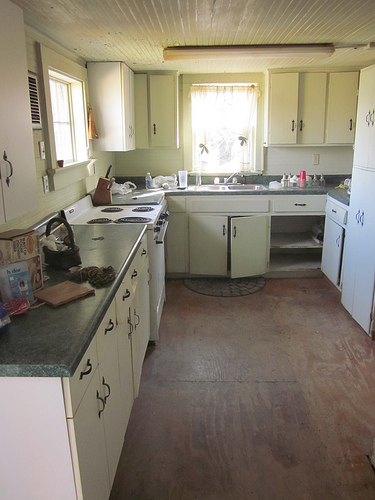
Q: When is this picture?
A: During the day.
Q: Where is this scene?
A: The kitchen.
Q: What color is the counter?
A: Green.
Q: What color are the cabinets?
A: White.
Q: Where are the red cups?
A: To the right of the sink.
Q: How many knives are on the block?
A: One.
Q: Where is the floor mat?
A: In front of the sink.